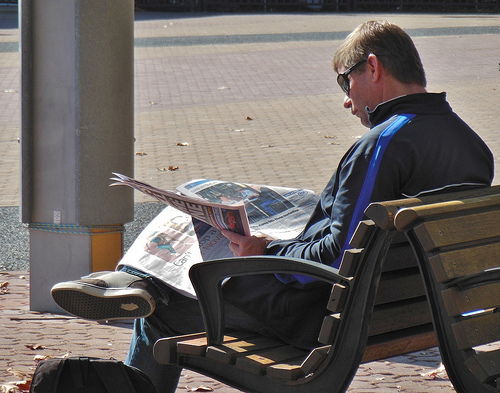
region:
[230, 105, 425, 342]
A man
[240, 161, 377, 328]
A man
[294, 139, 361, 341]
A man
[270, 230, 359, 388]
A man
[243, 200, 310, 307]
A man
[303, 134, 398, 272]
A man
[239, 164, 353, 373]
A manA man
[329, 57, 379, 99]
man wearing black sunglasses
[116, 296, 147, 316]
piece of chewing gum on the sole of a shoe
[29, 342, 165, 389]
a black bag on the ground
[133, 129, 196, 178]
dead leaves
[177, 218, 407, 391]
a wooden park bench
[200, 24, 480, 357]
man sitting on a park bench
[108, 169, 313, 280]
a newspaper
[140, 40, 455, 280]
man reading a newspaper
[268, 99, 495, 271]
man wearing a black windbreaker with a blue stipe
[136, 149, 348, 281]
man holding a newspaper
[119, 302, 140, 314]
white patch on sole of man's shoe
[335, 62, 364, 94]
man wearing dark sunglasses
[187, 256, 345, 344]
gray metal armrest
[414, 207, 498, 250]
wooden slat on bench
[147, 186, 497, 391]
bench next to a bench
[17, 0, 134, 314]
gray pillar in front of man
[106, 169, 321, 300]
man is treading a newspaper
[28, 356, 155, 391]
backpack on ground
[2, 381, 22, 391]
dry leaf on ground next to backpack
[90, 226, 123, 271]
yellow panel on pillar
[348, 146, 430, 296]
A man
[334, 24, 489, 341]
A man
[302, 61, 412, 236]
A man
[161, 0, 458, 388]
a man sitting on a bench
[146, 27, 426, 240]
a man reading a newpaper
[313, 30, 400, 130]
a man wearing sunglasses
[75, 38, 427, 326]
a man with his legs crossed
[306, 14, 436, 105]
a man with short hair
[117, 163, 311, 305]
a newspaper or magazine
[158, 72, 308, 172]
a brick side walk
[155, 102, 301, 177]
several brown leaves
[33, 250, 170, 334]
a man wearing tennis shoes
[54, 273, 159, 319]
black soles on a tennis shoe